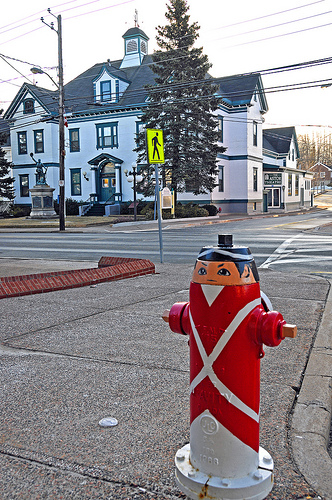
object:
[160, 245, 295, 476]
firehydrant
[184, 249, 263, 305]
character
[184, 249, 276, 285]
face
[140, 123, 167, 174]
sign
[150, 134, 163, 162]
man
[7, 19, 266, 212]
house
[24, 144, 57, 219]
statue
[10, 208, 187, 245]
ground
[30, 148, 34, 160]
something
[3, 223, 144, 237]
sidewalk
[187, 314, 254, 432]
x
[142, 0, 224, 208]
tree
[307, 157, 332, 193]
house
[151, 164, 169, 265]
metal pole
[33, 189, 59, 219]
base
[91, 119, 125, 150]
window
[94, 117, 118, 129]
trim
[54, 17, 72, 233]
telephone pole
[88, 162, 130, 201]
door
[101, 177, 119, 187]
glass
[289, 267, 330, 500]
curb